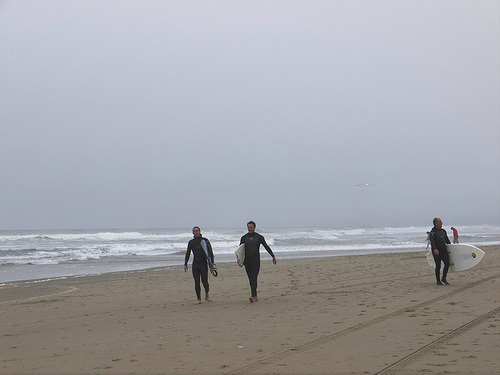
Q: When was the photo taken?
A: Daytime.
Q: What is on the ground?
A: Sand.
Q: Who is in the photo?
A: Four people.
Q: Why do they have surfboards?
A: They are going surfing.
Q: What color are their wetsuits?
A: Black.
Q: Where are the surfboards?
A: Under their arm.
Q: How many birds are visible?
A: One.